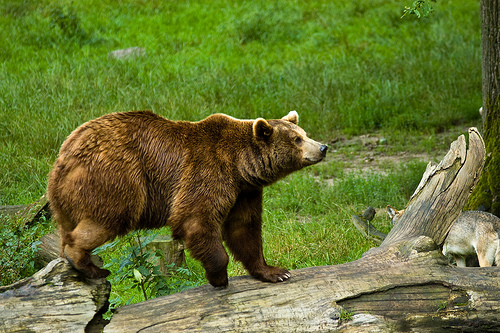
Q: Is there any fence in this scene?
A: No, there are no fences.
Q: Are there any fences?
A: No, there are no fences.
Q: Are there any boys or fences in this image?
A: No, there are no fences or boys.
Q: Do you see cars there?
A: No, there are no cars.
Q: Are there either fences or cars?
A: No, there are no cars or fences.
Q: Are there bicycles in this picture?
A: No, there are no bicycles.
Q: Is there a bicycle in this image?
A: No, there are no bicycles.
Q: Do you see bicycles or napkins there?
A: No, there are no bicycles or napkins.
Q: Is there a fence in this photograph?
A: No, there are no fences.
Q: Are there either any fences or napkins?
A: No, there are no fences or napkins.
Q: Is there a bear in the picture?
A: Yes, there is a bear.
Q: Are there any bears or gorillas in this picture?
A: Yes, there is a bear.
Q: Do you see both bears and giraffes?
A: No, there is a bear but no giraffes.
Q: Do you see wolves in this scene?
A: No, there are no wolves.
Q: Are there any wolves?
A: No, there are no wolves.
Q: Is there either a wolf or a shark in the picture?
A: No, there are no wolves or sharks.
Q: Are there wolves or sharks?
A: No, there are no wolves or sharks.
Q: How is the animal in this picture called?
A: The animal is a bear.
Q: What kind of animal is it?
A: The animal is a bear.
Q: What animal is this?
A: This is a bear.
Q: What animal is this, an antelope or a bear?
A: This is a bear.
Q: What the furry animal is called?
A: The animal is a bear.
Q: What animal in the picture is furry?
A: The animal is a bear.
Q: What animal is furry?
A: The animal is a bear.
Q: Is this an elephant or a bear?
A: This is a bear.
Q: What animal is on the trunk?
A: The bear is on the trunk.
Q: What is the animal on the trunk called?
A: The animal is a bear.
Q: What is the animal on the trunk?
A: The animal is a bear.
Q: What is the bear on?
A: The bear is on the trunk.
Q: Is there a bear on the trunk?
A: Yes, there is a bear on the trunk.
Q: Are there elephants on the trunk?
A: No, there is a bear on the trunk.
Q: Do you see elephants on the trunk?
A: No, there is a bear on the trunk.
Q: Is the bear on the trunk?
A: Yes, the bear is on the trunk.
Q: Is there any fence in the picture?
A: No, there are no fences.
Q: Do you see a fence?
A: No, there are no fences.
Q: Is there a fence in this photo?
A: No, there are no fences.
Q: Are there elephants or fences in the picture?
A: No, there are no fences or elephants.